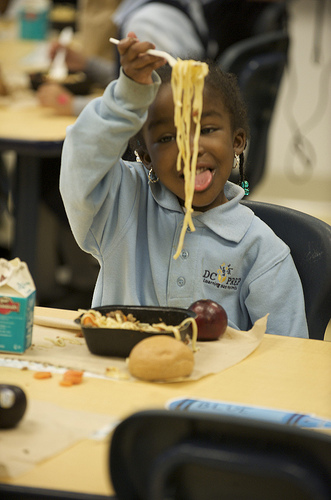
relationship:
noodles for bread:
[165, 58, 212, 263] [127, 336, 194, 383]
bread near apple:
[123, 331, 200, 385] [188, 299, 228, 342]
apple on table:
[188, 299, 228, 342] [0, 294, 326, 499]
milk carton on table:
[1, 256, 38, 359] [0, 294, 326, 499]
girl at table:
[53, 34, 311, 342] [0, 294, 326, 499]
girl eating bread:
[53, 34, 311, 342] [127, 336, 194, 383]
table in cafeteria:
[0, 294, 326, 499] [2, 3, 328, 499]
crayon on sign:
[164, 398, 329, 435] [159, 398, 329, 437]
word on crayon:
[195, 399, 255, 417] [164, 398, 329, 435]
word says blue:
[195, 399, 255, 417] [192, 399, 249, 419]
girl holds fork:
[53, 34, 311, 342] [109, 36, 209, 79]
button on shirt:
[174, 275, 190, 287] [53, 60, 308, 342]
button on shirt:
[178, 249, 192, 260] [53, 60, 308, 342]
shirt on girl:
[53, 60, 308, 342] [53, 34, 311, 342]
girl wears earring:
[53, 34, 311, 342] [144, 165, 162, 188]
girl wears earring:
[53, 34, 311, 342] [228, 155, 241, 172]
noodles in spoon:
[165, 58, 212, 263] [109, 36, 209, 79]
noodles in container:
[74, 306, 198, 345] [70, 301, 198, 362]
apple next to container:
[188, 299, 228, 342] [70, 301, 198, 362]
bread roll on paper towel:
[123, 331, 200, 385] [3, 304, 271, 389]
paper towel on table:
[3, 304, 271, 389] [0, 294, 326, 499]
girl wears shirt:
[53, 34, 311, 342] [53, 60, 308, 342]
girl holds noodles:
[53, 34, 311, 342] [165, 58, 212, 263]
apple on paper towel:
[183, 295, 230, 342] [3, 304, 271, 389]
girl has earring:
[53, 34, 311, 342] [144, 165, 162, 188]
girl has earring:
[53, 34, 311, 342] [228, 155, 241, 172]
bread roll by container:
[123, 331, 200, 385] [70, 301, 198, 362]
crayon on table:
[164, 398, 329, 435] [0, 294, 326, 499]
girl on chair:
[53, 34, 311, 342] [228, 198, 330, 343]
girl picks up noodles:
[53, 34, 311, 342] [165, 58, 212, 263]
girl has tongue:
[53, 34, 311, 342] [190, 170, 215, 193]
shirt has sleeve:
[53, 60, 308, 342] [46, 66, 167, 260]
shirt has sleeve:
[53, 60, 308, 342] [246, 252, 309, 342]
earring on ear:
[144, 165, 162, 188] [140, 147, 154, 170]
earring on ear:
[228, 155, 241, 172] [233, 128, 249, 155]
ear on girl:
[140, 147, 154, 170] [53, 34, 311, 342]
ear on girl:
[233, 128, 249, 155] [53, 34, 311, 342]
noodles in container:
[165, 58, 212, 263] [70, 301, 198, 362]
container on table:
[70, 301, 198, 362] [0, 294, 326, 499]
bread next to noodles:
[123, 331, 200, 385] [74, 306, 198, 345]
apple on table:
[183, 295, 230, 342] [0, 294, 326, 499]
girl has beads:
[53, 34, 311, 342] [238, 177, 250, 195]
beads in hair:
[238, 177, 250, 195] [155, 62, 249, 197]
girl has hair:
[53, 34, 311, 342] [155, 62, 249, 197]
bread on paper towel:
[127, 336, 194, 383] [3, 304, 271, 389]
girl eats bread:
[53, 34, 311, 342] [127, 336, 194, 383]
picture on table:
[159, 398, 329, 437] [0, 294, 326, 499]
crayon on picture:
[164, 398, 329, 435] [159, 398, 329, 437]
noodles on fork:
[165, 58, 212, 263] [109, 36, 209, 79]